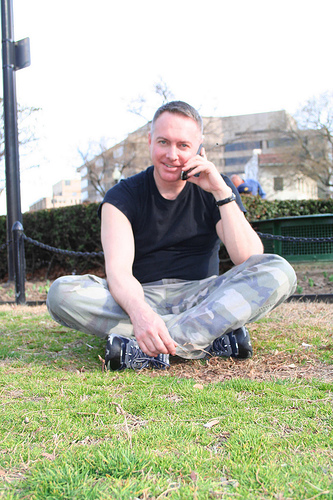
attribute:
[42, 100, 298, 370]
man — sitting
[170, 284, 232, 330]
camoflage — green, brown, black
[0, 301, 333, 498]
grass — green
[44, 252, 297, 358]
pants — camouflage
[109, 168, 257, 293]
shirt — black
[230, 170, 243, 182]
head — bald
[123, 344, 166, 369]
shoelaces — grey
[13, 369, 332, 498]
grass — green